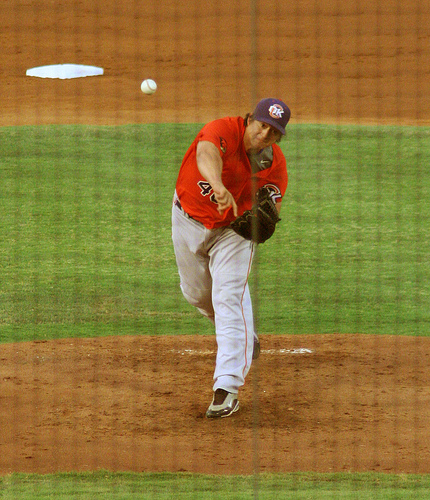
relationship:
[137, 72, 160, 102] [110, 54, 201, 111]
baseball in air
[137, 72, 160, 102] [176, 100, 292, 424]
baseball above pitcher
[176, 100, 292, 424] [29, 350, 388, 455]
player standing in dirt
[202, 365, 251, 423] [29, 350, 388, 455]
left foot of player standing in dirt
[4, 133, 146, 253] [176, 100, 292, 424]
grass behind player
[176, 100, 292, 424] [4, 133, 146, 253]
pitcher standing in front of grass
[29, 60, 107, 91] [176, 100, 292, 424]
base located behind pitcher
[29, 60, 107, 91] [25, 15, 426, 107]
base surrounded by dirt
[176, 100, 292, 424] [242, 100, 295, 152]
pitcher has a cap on h head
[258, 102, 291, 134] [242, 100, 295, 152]
cap on head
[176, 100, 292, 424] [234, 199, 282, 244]
pitcher has mitt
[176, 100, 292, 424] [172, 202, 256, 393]
pitcher has pants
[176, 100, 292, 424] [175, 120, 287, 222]
pitcher has red shirt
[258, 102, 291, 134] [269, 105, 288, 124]
cap has design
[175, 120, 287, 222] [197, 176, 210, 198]
red shirt has number 4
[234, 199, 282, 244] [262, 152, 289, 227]
mitt at end of left arm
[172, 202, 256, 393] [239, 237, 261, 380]
pants have red stripe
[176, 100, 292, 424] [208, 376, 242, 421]
pitcher has sneaker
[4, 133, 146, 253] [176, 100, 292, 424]
grass between base and pitcher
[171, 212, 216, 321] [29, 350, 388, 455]
pitcher's right leg above white spot on dirt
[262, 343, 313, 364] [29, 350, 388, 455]
white line covered in dirt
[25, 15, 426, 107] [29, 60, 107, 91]
dirt surrounds home mound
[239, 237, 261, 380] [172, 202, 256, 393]
red stripe on pitchers pants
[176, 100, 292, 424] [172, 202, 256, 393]
pitcher has on white uniform pants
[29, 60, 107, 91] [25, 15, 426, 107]
base embedded in dirt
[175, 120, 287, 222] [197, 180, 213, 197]
red shirt has black number 4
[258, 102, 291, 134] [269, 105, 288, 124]
cap has white design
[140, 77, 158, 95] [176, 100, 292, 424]
baseball thrown by pitcher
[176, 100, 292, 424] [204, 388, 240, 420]
pitcher wearing sneaker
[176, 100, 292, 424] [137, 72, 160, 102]
pitcher throwing baseball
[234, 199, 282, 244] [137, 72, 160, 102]
glove for throwing baseball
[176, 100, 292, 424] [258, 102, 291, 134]
pitcher wearing cap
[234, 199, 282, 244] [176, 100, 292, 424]
mitt held in hand of pitcher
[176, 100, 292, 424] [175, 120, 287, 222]
pitcher has on red shirt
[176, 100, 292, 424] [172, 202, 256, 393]
pitcher has on grey pants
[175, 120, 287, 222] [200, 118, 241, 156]
red shirt has short sleeve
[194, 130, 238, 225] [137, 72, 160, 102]
pitcher's arm throwing baseball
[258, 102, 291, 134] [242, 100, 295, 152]
blue cap on pitcher's head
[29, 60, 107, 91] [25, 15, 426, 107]
base sits atop dirt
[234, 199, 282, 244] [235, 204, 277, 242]
mitt made of leather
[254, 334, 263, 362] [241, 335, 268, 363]
cleat on pitcher's foot